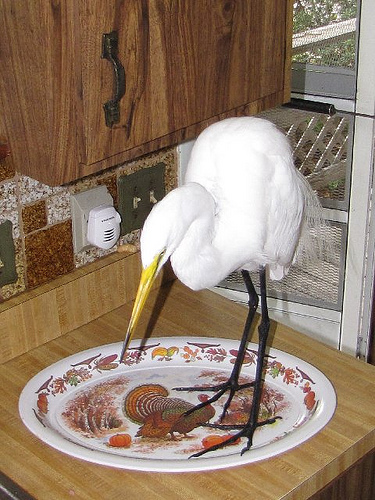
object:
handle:
[100, 29, 126, 130]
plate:
[17, 335, 336, 474]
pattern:
[60, 374, 132, 439]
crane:
[117, 113, 341, 461]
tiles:
[0, 148, 177, 304]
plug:
[70, 184, 123, 255]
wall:
[0, 130, 184, 365]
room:
[0, 1, 374, 499]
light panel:
[115, 161, 166, 237]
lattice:
[277, 115, 350, 178]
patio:
[290, 0, 362, 104]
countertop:
[0, 277, 373, 500]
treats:
[18, 335, 337, 474]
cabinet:
[0, 1, 292, 188]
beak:
[118, 260, 162, 365]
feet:
[186, 410, 283, 459]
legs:
[249, 265, 272, 415]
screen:
[214, 0, 360, 314]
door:
[188, 0, 375, 362]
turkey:
[123, 382, 216, 444]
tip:
[119, 333, 134, 364]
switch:
[132, 195, 141, 209]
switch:
[149, 191, 158, 204]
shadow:
[133, 255, 179, 360]